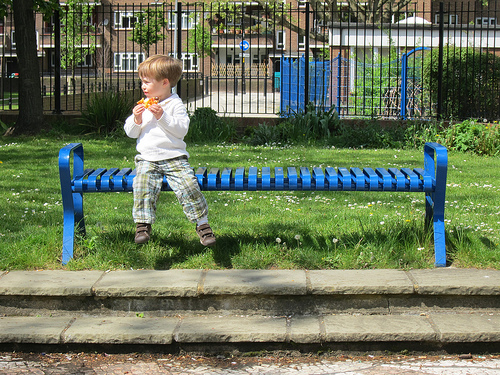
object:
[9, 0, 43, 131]
trunk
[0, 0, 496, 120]
fence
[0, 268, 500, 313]
steps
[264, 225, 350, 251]
dendelions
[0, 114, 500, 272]
grass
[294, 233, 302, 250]
white flower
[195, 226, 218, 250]
shoe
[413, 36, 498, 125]
bush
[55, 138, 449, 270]
bench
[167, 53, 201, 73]
window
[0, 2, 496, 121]
building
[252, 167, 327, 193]
metal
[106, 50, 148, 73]
window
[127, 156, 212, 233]
pants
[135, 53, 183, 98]
head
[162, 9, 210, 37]
window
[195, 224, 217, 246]
foot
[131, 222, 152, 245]
foot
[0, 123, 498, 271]
ground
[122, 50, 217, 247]
boy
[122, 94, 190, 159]
white shirt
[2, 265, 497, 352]
staircase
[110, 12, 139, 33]
window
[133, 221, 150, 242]
shoe